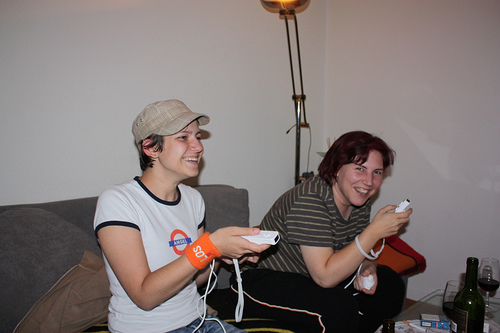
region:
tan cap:
[128, 95, 210, 142]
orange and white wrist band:
[182, 230, 223, 275]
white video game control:
[228, 222, 284, 324]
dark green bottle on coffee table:
[448, 254, 487, 331]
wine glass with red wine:
[478, 252, 498, 322]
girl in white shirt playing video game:
[91, 94, 251, 331]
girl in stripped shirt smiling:
[233, 126, 416, 331]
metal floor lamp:
[259, 0, 310, 186]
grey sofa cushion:
[0, 206, 104, 331]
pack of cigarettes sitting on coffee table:
[417, 311, 454, 331]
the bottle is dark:
[444, 239, 491, 328]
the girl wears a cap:
[117, 77, 212, 136]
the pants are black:
[261, 273, 314, 319]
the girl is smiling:
[322, 112, 386, 216]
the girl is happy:
[115, 86, 222, 191]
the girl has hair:
[325, 137, 362, 159]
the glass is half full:
[481, 255, 497, 295]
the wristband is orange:
[189, 228, 218, 274]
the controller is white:
[211, 219, 292, 254]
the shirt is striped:
[291, 180, 331, 247]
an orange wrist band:
[183, 229, 218, 273]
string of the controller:
[232, 260, 247, 323]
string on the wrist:
[342, 225, 383, 265]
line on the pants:
[232, 284, 339, 331]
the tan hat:
[125, 82, 222, 136]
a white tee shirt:
[87, 175, 211, 331]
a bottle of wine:
[452, 252, 483, 332]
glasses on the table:
[435, 257, 498, 327]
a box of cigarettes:
[417, 314, 451, 331]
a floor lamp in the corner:
[263, 0, 311, 180]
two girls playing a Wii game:
[98, 95, 470, 287]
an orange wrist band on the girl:
[175, 228, 232, 280]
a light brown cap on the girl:
[123, 92, 205, 174]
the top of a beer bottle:
[445, 244, 491, 331]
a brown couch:
[0, 196, 104, 331]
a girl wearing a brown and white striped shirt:
[262, 179, 376, 277]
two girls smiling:
[142, 111, 390, 208]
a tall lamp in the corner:
[269, 5, 318, 167]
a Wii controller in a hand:
[225, 221, 287, 253]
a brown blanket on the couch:
[23, 249, 113, 331]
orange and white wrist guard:
[145, 222, 227, 294]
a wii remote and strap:
[213, 212, 277, 332]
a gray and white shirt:
[262, 185, 338, 289]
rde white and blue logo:
[151, 214, 205, 281]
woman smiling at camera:
[291, 128, 410, 226]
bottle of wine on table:
[422, 235, 478, 306]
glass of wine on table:
[466, 245, 493, 308]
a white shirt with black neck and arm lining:
[105, 182, 217, 313]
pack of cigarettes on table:
[417, 297, 454, 331]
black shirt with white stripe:
[234, 265, 407, 321]